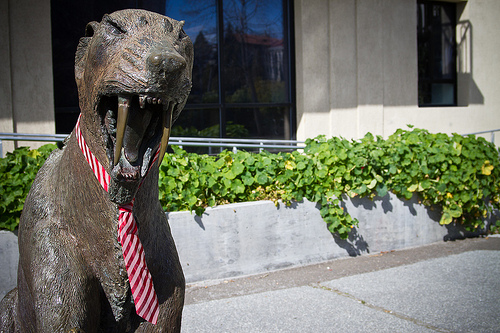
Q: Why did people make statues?
A: Art.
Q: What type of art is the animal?
A: Sculpture.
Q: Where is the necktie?
A: On the sculpture.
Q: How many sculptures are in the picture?
A: One.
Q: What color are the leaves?
A: Green.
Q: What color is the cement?
A: Gray.